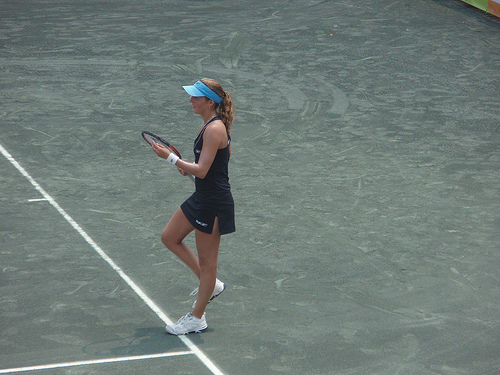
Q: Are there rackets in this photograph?
A: Yes, there is a racket.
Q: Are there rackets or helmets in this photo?
A: Yes, there is a racket.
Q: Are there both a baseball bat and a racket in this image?
A: No, there is a racket but no baseball bats.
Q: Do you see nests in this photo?
A: No, there are no nests.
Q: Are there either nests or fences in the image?
A: No, there are no nests or fences.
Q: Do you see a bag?
A: No, there are no bags.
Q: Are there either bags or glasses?
A: No, there are no bags or glasses.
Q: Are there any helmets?
A: No, there are no helmets.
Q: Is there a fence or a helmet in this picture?
A: No, there are no helmets or fences.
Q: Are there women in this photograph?
A: Yes, there is a woman.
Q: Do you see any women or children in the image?
A: Yes, there is a woman.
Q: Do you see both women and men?
A: No, there is a woman but no men.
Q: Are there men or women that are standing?
A: Yes, the woman is standing.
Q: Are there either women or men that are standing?
A: Yes, the woman is standing.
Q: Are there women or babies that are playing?
A: Yes, the woman is playing.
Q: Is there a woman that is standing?
A: Yes, there is a woman that is standing.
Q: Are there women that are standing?
A: Yes, there is a woman that is standing.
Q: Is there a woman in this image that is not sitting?
A: Yes, there is a woman that is standing.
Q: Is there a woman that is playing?
A: Yes, there is a woman that is playing.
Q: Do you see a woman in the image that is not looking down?
A: Yes, there is a woman that is playing .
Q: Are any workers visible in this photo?
A: No, there are no workers.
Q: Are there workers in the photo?
A: No, there are no workers.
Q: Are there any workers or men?
A: No, there are no workers or men.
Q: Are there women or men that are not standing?
A: No, there is a woman but she is standing.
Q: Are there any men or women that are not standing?
A: No, there is a woman but she is standing.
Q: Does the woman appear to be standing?
A: Yes, the woman is standing.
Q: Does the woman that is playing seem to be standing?
A: Yes, the woman is standing.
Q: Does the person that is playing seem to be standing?
A: Yes, the woman is standing.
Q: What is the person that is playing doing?
A: The woman is standing.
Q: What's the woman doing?
A: The woman is standing.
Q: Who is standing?
A: The woman is standing.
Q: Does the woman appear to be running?
A: No, the woman is standing.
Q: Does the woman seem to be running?
A: No, the woman is standing.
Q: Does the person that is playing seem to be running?
A: No, the woman is standing.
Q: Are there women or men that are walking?
A: No, there is a woman but she is standing.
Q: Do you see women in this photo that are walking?
A: No, there is a woman but she is standing.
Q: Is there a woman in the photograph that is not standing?
A: No, there is a woman but she is standing.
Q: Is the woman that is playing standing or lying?
A: The woman is standing.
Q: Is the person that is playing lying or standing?
A: The woman is standing.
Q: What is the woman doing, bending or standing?
A: The woman is standing.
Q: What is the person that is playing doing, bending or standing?
A: The woman is standing.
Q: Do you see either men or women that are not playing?
A: No, there is a woman but she is playing.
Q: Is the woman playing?
A: Yes, the woman is playing.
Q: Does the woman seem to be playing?
A: Yes, the woman is playing.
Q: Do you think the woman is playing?
A: Yes, the woman is playing.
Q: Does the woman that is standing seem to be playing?
A: Yes, the woman is playing.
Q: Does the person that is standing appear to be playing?
A: Yes, the woman is playing.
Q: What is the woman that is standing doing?
A: The woman is playing.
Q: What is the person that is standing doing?
A: The woman is playing.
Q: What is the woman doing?
A: The woman is playing.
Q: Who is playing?
A: The woman is playing.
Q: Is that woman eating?
A: No, the woman is playing.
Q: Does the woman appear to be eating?
A: No, the woman is playing.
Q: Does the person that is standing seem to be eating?
A: No, the woman is playing.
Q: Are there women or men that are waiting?
A: No, there is a woman but she is playing.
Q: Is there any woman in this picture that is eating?
A: No, there is a woman but she is playing.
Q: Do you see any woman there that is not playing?
A: No, there is a woman but she is playing.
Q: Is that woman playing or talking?
A: The woman is playing.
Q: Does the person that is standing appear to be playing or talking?
A: The woman is playing.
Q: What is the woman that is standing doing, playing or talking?
A: The woman is playing.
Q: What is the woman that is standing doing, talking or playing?
A: The woman is playing.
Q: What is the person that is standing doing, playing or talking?
A: The woman is playing.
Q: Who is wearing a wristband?
A: The woman is wearing a wristband.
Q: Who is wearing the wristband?
A: The woman is wearing a wristband.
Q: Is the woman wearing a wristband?
A: Yes, the woman is wearing a wristband.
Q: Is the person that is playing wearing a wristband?
A: Yes, the woman is wearing a wristband.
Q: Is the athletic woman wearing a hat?
A: No, the woman is wearing a wristband.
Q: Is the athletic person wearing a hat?
A: No, the woman is wearing a wristband.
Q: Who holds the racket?
A: The woman holds the tennis racket.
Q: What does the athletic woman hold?
A: The woman holds the tennis racket.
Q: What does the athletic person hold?
A: The woman holds the tennis racket.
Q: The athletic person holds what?
A: The woman holds the tennis racket.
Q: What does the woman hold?
A: The woman holds the tennis racket.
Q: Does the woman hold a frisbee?
A: No, the woman holds the racket.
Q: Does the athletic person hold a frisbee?
A: No, the woman holds the racket.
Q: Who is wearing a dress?
A: The woman is wearing a dress.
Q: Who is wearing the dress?
A: The woman is wearing a dress.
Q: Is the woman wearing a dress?
A: Yes, the woman is wearing a dress.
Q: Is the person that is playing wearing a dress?
A: Yes, the woman is wearing a dress.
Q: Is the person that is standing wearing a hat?
A: No, the woman is wearing a dress.